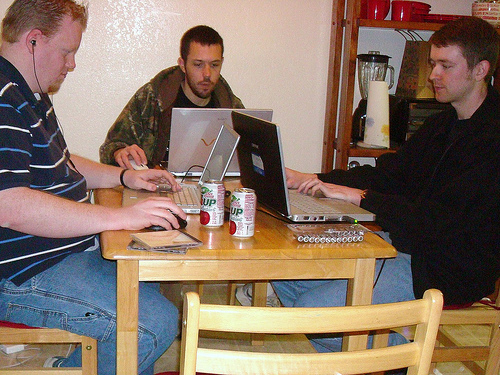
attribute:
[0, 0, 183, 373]
man — seated, watching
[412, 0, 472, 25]
dishes — red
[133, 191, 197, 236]
mouse — black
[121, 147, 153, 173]
mouse — black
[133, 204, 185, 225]
mouse — black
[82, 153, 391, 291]
table — wooden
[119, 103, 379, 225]
laptops — three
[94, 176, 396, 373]
table — wooden, brown, dining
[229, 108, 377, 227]
laptop — black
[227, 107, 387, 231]
laptop — black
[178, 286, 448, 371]
chair — wooden, wood